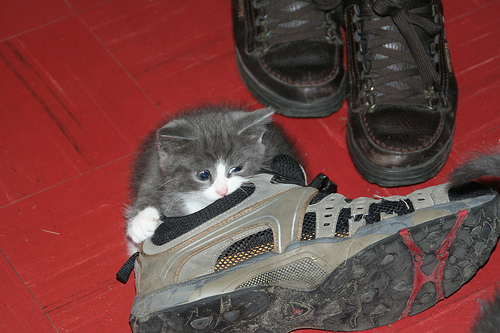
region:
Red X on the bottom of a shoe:
[395, 208, 467, 322]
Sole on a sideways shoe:
[101, 191, 498, 331]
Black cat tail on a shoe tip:
[450, 150, 496, 182]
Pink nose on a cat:
[217, 185, 227, 196]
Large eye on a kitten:
[197, 170, 210, 181]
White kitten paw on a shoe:
[124, 205, 170, 242]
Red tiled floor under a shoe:
[1, 2, 140, 332]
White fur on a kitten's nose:
[216, 160, 226, 186]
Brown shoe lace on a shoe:
[373, 0, 439, 82]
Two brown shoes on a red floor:
[227, 2, 459, 189]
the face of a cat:
[179, 140, 253, 195]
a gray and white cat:
[141, 99, 298, 219]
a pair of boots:
[233, 0, 458, 180]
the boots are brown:
[231, 0, 458, 180]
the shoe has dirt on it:
[131, 168, 495, 328]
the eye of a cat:
[194, 169, 214, 181]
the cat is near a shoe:
[130, 102, 295, 247]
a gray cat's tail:
[450, 143, 498, 184]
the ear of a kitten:
[154, 115, 199, 156]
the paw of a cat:
[131, 205, 161, 242]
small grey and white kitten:
[116, 85, 323, 265]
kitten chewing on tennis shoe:
[112, 79, 332, 256]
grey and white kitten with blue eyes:
[119, 91, 316, 274]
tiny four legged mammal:
[119, 92, 320, 257]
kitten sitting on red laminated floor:
[118, 88, 323, 263]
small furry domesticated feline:
[113, 95, 320, 251]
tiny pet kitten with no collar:
[117, 95, 319, 261]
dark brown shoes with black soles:
[216, 0, 478, 192]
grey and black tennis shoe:
[117, 174, 497, 330]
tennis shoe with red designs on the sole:
[126, 165, 498, 326]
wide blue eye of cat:
[197, 169, 212, 183]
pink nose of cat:
[215, 185, 227, 197]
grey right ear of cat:
[151, 127, 191, 152]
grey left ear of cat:
[235, 105, 276, 132]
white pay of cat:
[129, 213, 166, 235]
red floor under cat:
[4, 8, 237, 325]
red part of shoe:
[390, 203, 469, 322]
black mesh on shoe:
[212, 225, 276, 272]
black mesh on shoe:
[295, 214, 316, 240]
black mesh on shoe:
[332, 205, 361, 239]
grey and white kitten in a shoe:
[127, 103, 306, 241]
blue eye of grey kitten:
[191, 165, 211, 182]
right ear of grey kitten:
[154, 122, 199, 162]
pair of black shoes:
[230, 2, 461, 182]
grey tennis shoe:
[122, 165, 487, 330]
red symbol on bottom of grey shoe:
[400, 209, 467, 319]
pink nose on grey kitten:
[213, 183, 230, 195]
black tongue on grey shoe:
[272, 151, 304, 185]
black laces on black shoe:
[365, 6, 430, 114]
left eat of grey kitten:
[231, 113, 276, 145]